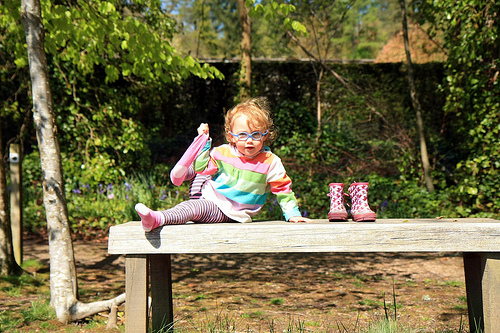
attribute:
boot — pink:
[329, 181, 347, 222]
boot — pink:
[347, 181, 376, 222]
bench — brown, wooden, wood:
[106, 217, 499, 332]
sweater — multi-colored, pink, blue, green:
[195, 139, 302, 222]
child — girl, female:
[127, 97, 307, 231]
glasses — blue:
[228, 131, 269, 141]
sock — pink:
[168, 129, 208, 187]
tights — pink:
[157, 166, 236, 225]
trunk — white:
[25, 3, 123, 316]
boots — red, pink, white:
[325, 180, 375, 222]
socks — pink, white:
[135, 126, 208, 235]